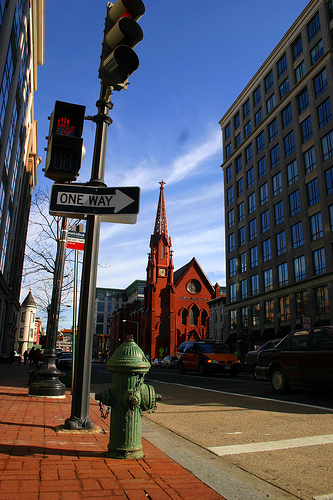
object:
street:
[280, 402, 331, 494]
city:
[0, 0, 332, 499]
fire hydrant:
[94, 333, 162, 459]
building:
[142, 178, 229, 367]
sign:
[48, 184, 141, 216]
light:
[55, 111, 75, 142]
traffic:
[85, 323, 333, 403]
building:
[217, 0, 332, 352]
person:
[22, 348, 30, 366]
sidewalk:
[0, 351, 76, 499]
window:
[189, 305, 198, 326]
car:
[253, 324, 333, 399]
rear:
[254, 337, 292, 390]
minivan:
[175, 344, 241, 377]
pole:
[63, 0, 145, 428]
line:
[206, 432, 333, 457]